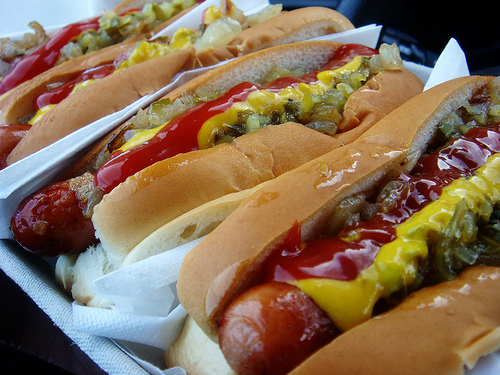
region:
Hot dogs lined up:
[0, 0, 498, 372]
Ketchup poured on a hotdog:
[258, 115, 498, 280]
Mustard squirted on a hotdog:
[296, 152, 498, 327]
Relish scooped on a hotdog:
[372, 189, 497, 312]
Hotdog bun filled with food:
[160, 70, 498, 374]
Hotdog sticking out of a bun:
[202, 278, 342, 374]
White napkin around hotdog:
[0, 59, 240, 373]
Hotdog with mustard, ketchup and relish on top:
[176, 74, 498, 374]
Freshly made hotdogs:
[0, 0, 498, 373]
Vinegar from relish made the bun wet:
[232, 128, 407, 215]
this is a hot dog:
[190, 75, 497, 372]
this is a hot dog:
[23, 42, 385, 254]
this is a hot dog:
[1, 4, 297, 166]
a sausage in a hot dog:
[214, 109, 498, 369]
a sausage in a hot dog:
[0, 54, 374, 243]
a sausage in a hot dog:
[2, 5, 271, 189]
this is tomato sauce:
[275, 230, 364, 295]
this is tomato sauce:
[438, 121, 485, 183]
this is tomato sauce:
[77, 140, 189, 190]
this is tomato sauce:
[26, 55, 106, 112]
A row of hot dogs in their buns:
[27, 20, 484, 362]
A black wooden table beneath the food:
[0, 309, 72, 370]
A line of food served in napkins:
[13, 12, 473, 355]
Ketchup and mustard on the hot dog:
[271, 135, 491, 295]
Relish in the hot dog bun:
[424, 228, 498, 294]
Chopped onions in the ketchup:
[334, 183, 408, 226]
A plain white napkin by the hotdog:
[83, 265, 190, 343]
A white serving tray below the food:
[8, 256, 130, 368]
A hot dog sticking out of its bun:
[21, 186, 98, 256]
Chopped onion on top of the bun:
[364, 38, 408, 82]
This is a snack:
[11, 138, 140, 273]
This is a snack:
[121, 106, 228, 224]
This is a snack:
[0, 28, 97, 146]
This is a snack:
[92, 20, 214, 139]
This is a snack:
[269, 203, 407, 373]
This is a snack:
[91, 231, 219, 367]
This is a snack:
[383, 19, 498, 223]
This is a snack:
[389, 214, 491, 356]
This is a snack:
[258, 15, 400, 160]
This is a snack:
[93, 5, 297, 155]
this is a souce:
[291, 226, 381, 298]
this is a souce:
[356, 185, 433, 265]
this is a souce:
[91, 127, 232, 182]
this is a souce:
[220, 65, 330, 127]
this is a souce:
[20, 75, 145, 112]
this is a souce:
[452, 129, 491, 216]